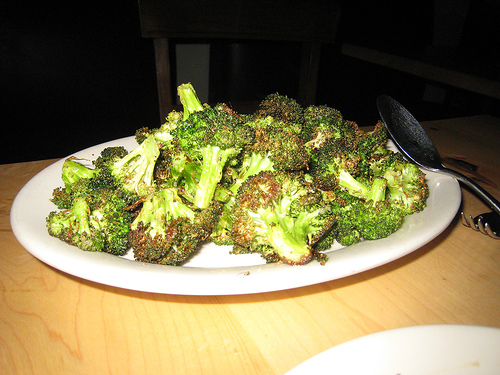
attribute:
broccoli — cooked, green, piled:
[46, 81, 431, 267]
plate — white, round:
[7, 126, 465, 300]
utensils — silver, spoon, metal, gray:
[375, 91, 500, 216]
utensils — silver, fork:
[457, 208, 500, 241]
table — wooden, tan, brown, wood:
[2, 107, 499, 375]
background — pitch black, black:
[1, 2, 233, 165]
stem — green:
[175, 81, 206, 120]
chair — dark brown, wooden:
[136, 1, 341, 131]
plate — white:
[276, 322, 499, 374]